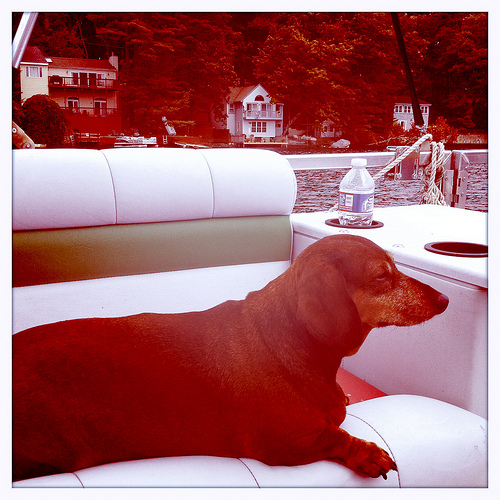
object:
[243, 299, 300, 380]
wrinkle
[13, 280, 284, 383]
dog's back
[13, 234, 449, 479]
dog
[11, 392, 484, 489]
cushion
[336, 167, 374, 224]
water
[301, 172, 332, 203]
wave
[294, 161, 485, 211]
water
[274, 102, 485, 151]
ground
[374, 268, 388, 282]
dog eye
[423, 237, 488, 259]
cup holder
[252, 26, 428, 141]
trees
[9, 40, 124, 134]
house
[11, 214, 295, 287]
cushion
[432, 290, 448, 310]
nose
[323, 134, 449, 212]
rope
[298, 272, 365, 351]
ear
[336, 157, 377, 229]
bottle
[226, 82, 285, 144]
house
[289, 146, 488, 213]
lake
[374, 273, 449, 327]
muzzle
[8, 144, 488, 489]
seat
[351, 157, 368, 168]
top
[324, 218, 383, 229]
cup holder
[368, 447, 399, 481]
claw